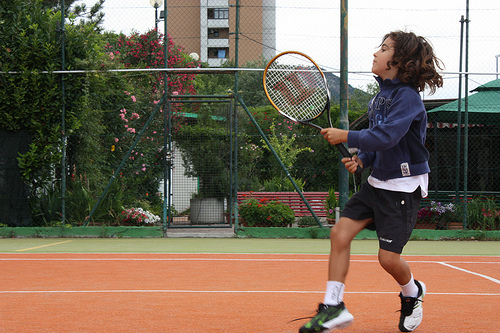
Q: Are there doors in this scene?
A: Yes, there is a door.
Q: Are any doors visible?
A: Yes, there is a door.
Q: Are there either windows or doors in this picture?
A: Yes, there is a door.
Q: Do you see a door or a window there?
A: Yes, there is a door.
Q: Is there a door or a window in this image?
A: Yes, there is a door.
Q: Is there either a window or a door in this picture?
A: Yes, there is a door.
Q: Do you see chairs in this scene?
A: No, there are no chairs.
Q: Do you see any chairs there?
A: No, there are no chairs.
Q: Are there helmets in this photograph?
A: No, there are no helmets.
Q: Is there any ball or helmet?
A: No, there are no helmets or balls.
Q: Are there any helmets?
A: No, there are no helmets.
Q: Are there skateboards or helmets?
A: No, there are no helmets or skateboards.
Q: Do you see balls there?
A: No, there are no balls.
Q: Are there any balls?
A: No, there are no balls.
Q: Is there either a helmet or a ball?
A: No, there are no balls or helmets.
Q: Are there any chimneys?
A: No, there are no chimneys.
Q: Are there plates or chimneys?
A: No, there are no chimneys or plates.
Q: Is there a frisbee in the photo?
A: No, there are no frisbees.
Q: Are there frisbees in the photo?
A: No, there are no frisbees.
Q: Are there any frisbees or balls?
A: No, there are no frisbees or balls.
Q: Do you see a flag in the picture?
A: No, there are no flags.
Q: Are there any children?
A: Yes, there is a child.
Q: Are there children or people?
A: Yes, there is a child.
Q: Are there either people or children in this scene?
A: Yes, there is a child.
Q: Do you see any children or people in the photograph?
A: Yes, there is a child.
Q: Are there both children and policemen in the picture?
A: No, there is a child but no policemen.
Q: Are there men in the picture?
A: No, there are no men.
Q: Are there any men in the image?
A: No, there are no men.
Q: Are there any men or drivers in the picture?
A: No, there are no men or drivers.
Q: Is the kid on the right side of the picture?
A: Yes, the kid is on the right of the image.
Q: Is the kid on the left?
A: No, the kid is on the right of the image.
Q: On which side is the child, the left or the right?
A: The child is on the right of the image.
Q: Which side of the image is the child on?
A: The child is on the right of the image.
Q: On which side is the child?
A: The child is on the right of the image.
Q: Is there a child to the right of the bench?
A: Yes, there is a child to the right of the bench.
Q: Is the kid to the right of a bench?
A: Yes, the kid is to the right of a bench.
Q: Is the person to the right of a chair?
A: No, the child is to the right of a bench.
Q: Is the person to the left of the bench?
A: No, the child is to the right of the bench.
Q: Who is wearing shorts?
A: The kid is wearing shorts.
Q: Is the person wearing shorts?
A: Yes, the child is wearing shorts.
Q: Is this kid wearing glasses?
A: No, the kid is wearing shorts.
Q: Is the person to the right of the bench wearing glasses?
A: No, the kid is wearing shorts.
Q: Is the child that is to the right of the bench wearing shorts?
A: Yes, the child is wearing shorts.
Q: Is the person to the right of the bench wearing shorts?
A: Yes, the child is wearing shorts.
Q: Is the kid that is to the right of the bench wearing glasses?
A: No, the child is wearing shorts.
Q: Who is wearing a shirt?
A: The child is wearing a shirt.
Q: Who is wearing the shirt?
A: The child is wearing a shirt.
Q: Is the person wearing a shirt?
A: Yes, the kid is wearing a shirt.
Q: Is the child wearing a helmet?
A: No, the child is wearing a shirt.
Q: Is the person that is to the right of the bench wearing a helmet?
A: No, the child is wearing a shirt.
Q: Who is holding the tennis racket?
A: The child is holding the tennis racket.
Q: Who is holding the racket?
A: The child is holding the tennis racket.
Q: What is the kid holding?
A: The kid is holding the tennis racket.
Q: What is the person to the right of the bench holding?
A: The kid is holding the tennis racket.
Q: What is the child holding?
A: The kid is holding the tennis racket.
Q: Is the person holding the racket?
A: Yes, the kid is holding the racket.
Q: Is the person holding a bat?
A: No, the kid is holding the racket.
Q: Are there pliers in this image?
A: No, there are no pliers.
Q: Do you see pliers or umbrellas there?
A: No, there are no pliers or umbrellas.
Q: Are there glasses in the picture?
A: No, there are no glasses.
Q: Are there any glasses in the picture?
A: No, there are no glasses.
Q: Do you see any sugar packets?
A: No, there are no sugar packets.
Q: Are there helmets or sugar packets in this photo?
A: No, there are no sugar packets or helmets.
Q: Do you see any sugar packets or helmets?
A: No, there are no sugar packets or helmets.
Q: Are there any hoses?
A: No, there are no hoses.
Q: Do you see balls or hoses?
A: No, there are no hoses or balls.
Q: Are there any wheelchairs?
A: No, there are no wheelchairs.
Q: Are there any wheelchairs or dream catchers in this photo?
A: No, there are no wheelchairs or dream catchers.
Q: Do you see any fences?
A: Yes, there is a fence.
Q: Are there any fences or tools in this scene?
A: Yes, there is a fence.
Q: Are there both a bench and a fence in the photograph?
A: Yes, there are both a fence and a bench.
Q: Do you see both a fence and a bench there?
A: Yes, there are both a fence and a bench.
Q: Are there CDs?
A: No, there are no cds.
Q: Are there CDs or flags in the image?
A: No, there are no CDs or flags.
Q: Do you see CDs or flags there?
A: No, there are no CDs or flags.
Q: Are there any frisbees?
A: No, there are no frisbees.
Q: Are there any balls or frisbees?
A: No, there are no frisbees or balls.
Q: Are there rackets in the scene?
A: Yes, there is a racket.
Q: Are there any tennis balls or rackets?
A: Yes, there is a racket.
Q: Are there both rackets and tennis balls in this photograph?
A: No, there is a racket but no tennis balls.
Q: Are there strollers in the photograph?
A: No, there are no strollers.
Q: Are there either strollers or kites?
A: No, there are no strollers or kites.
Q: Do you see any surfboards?
A: No, there are no surfboards.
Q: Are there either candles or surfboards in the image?
A: No, there are no surfboards or candles.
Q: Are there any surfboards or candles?
A: No, there are no surfboards or candles.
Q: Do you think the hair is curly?
A: Yes, the hair is curly.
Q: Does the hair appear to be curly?
A: Yes, the hair is curly.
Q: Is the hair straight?
A: No, the hair is curly.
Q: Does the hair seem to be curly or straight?
A: The hair is curly.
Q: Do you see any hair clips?
A: No, there are no hair clips.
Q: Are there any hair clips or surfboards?
A: No, there are no hair clips or surfboards.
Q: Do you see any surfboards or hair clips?
A: No, there are no hair clips or surfboards.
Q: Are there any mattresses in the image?
A: No, there are no mattresses.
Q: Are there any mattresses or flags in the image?
A: No, there are no mattresses or flags.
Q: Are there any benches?
A: Yes, there is a bench.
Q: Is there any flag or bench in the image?
A: Yes, there is a bench.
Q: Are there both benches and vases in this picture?
A: No, there is a bench but no vases.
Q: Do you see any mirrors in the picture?
A: No, there are no mirrors.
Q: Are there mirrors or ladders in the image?
A: No, there are no mirrors or ladders.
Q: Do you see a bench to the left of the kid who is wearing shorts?
A: Yes, there is a bench to the left of the kid.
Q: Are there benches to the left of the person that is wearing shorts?
A: Yes, there is a bench to the left of the kid.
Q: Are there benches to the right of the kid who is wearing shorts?
A: No, the bench is to the left of the child.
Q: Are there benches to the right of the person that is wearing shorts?
A: No, the bench is to the left of the child.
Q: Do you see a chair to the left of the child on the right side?
A: No, there is a bench to the left of the child.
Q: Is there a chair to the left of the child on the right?
A: No, there is a bench to the left of the child.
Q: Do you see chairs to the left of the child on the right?
A: No, there is a bench to the left of the child.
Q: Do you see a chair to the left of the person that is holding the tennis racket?
A: No, there is a bench to the left of the child.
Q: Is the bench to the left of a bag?
A: No, the bench is to the left of the child.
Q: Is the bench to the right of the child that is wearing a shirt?
A: No, the bench is to the left of the child.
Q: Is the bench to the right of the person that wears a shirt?
A: No, the bench is to the left of the child.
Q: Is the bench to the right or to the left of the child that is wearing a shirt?
A: The bench is to the left of the child.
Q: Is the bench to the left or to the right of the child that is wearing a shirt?
A: The bench is to the left of the child.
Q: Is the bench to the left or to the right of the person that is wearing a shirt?
A: The bench is to the left of the child.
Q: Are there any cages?
A: No, there are no cages.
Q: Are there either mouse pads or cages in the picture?
A: No, there are no cages or mouse pads.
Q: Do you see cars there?
A: No, there are no cars.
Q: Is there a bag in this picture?
A: No, there are no bags.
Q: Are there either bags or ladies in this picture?
A: No, there are no bags or ladies.